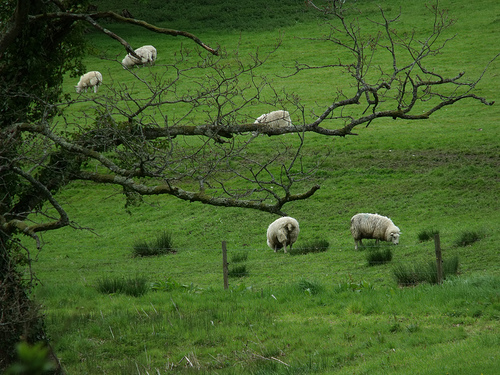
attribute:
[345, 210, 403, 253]
sheep — whitish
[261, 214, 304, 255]
sheep — whitish, oval-shaped, giving rear view, expressing boredom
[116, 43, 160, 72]
sheep — whitish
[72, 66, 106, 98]
sheep — whitish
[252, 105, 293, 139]
sheep — whitish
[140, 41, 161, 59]
sheep — whitish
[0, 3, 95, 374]
tree — large, grey-green, gnarled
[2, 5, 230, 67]
branch — long, leafless @ far end, gnarly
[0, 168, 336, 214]
branch — long, leafless @ far end, gnarly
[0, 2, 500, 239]
branch — long, leafless @ far end, gnarly, very grey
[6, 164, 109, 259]
branch — gnarly, brackish green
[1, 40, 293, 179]
branch — long, leafless @ far end, gnarly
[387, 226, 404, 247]
head — down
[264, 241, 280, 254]
head — down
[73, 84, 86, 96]
head — down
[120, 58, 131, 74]
head — down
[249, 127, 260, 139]
head — down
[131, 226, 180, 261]
patch — high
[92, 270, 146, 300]
patch — high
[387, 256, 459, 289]
patch — high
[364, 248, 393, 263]
patch — high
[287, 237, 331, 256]
patch — high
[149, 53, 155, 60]
'turkerworker — unpayable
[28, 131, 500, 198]
grass — muddy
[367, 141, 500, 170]
mud — brown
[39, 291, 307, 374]
grass — dry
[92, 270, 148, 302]
grass — darker green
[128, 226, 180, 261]
grass — darker green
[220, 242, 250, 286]
grass — darker green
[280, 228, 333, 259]
grass — darker green, high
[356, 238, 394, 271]
grass — darker green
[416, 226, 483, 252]
grass — darker green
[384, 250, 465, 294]
grass — darker green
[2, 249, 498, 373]
grass — longer in front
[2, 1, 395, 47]
grass — deep green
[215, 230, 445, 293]
poles — wooden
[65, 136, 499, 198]
soil — patch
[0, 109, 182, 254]
bush — maybe vine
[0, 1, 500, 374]
scene — rural, in daylight, maybe autumn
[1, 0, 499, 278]
branches — gnarled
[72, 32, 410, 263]
sheep — scattered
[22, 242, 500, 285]
wire fencing — maybe existing, maybe invisible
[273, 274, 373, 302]
grass — high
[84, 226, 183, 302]
grass — high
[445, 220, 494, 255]
grass — high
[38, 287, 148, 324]
grass — high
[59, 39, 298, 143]
sheep — three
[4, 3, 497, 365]
grass — of course, green, patch